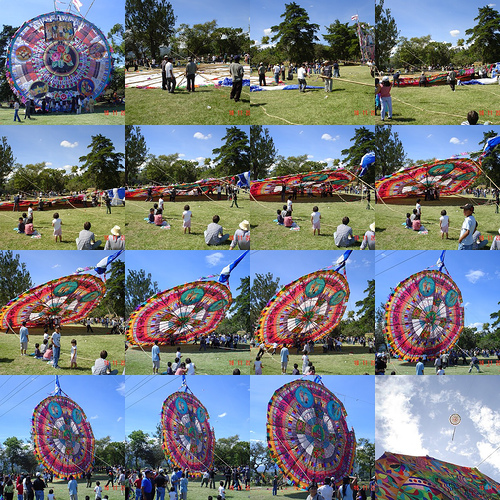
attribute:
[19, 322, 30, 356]
person — standing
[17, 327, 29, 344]
shirt — blue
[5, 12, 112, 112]
kite — large, round, multicolored, colorful, big, circular, blue, white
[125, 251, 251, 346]
kite — large, round, multicolored, big, circular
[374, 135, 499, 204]
kite — large, multicolored, colorful, big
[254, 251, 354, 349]
kite — large, round, multicolored, colorful, big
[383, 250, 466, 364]
kite — large, multicolored, colorful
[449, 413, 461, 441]
kite — small, multicolored, flying, yellow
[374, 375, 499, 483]
sky — blue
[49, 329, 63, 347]
shirt — white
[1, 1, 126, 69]
sky — blue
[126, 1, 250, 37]
sky — blue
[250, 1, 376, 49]
sky — blue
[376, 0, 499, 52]
sky — blue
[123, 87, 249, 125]
grass — green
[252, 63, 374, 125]
grass — green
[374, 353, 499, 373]
grass — green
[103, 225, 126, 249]
person — sitting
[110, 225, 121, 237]
hat — tan, white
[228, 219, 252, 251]
person — sitting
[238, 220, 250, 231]
hat — tan, white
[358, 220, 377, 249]
person — sitting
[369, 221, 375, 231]
hat — white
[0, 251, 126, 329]
kite — multicolored, large, circular, yellow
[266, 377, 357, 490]
kite — multicolored, large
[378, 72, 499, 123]
grass — green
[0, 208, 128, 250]
grass — green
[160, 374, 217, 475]
kite — round, large, multicolored, circular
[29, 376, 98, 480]
kite — round, multicolored, large, circular, white, blue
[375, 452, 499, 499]
kite — multicolored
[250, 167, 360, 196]
kite — multicolored, large, colorful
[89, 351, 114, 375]
person — sitting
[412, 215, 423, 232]
person — sitting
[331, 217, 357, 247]
person — sitting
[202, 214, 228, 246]
person — sitting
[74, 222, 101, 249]
person — sitting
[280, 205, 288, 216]
person — sitting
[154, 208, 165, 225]
person — sitting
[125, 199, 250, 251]
grass — green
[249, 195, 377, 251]
grass — green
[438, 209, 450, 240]
kid — little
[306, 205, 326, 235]
kid — little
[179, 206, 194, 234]
kid — little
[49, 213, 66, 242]
kid — little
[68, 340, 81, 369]
kid — little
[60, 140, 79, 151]
cloud — patchy, white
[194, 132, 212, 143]
cloud — patchy, white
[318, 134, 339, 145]
cloud — patchy, white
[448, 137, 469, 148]
cloud — patchy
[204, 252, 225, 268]
cloud — patchy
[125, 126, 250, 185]
trees — green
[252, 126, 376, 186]
trees — green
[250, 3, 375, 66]
trees — green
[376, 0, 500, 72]
trees — green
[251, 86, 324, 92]
cloth — blue, white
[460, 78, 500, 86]
cloth — white, blue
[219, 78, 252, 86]
cloth — blue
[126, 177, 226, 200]
kite — big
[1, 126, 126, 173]
sky — blue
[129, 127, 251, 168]
sky — blue